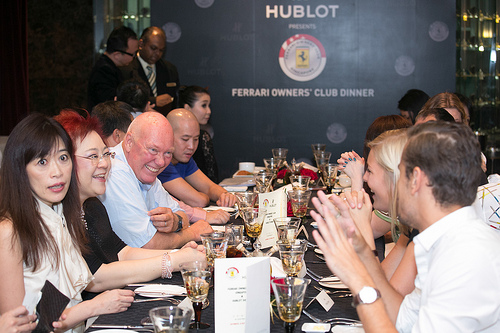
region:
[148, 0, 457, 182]
that's a sign on the wall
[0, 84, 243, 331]
there are five people sitting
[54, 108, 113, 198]
this lady has red hair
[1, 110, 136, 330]
this lady has long brown hair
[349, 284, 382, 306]
he has a watch on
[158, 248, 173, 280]
she has on some bracelets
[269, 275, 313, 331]
this is a wine glass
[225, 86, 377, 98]
this is the name of the club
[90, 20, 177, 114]
two men are talking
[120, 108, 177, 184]
this man has a bald head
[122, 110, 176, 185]
A bald man smiling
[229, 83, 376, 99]
'Ferrari Owners' Club Dinner' sign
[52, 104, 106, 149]
Red dyed color hair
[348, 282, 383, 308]
Round face wrist watch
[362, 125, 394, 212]
A blonde hair woman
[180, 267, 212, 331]
A clear glass of wine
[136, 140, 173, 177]
A man smiling face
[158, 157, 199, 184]
A navy blue short sleeves shirt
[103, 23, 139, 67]
Man wearing eye glasses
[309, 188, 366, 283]
Male hands in the air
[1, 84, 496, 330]
people sitting at a long table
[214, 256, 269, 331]
a white menu on a table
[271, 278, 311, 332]
a glass of white wine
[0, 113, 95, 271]
woman with long brown hair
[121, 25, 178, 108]
man wearing a suit and a tie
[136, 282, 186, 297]
a small white plate on a table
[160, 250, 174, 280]
woman wearing a bracelet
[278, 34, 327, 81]
a white and red logo on a blue wall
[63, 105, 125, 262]
woman with red hair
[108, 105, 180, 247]
man wearing light blue shirt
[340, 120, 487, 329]
man wearing a watch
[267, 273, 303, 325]
wine glass on table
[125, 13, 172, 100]
man wearing suit and tie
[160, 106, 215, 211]
man wearing dark blue shirt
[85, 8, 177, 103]
two men having a conversation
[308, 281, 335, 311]
name card on the table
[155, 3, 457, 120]
black sign with white letters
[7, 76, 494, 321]
a group of people at a table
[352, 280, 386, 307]
a watch on a man's wrist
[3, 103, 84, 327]
a lady with long dark hair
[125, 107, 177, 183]
a bald man's head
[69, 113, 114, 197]
the head of a lady wearing glasses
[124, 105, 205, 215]
2 bald men sitting together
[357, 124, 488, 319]
a man and woman enjoying themselves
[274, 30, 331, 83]
a Ferrari emblem on the wall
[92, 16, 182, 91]
2 men talking to each other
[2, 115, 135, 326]
a person is sitting down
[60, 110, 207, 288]
a person is sitting down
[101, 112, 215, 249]
a person is sitting down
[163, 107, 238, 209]
a person is sitting down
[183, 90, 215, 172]
a person is sitting down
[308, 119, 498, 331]
a person is sitting down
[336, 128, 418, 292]
a person is sitting down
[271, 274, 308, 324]
a vessel made for drinking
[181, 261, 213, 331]
a vessel made for drinking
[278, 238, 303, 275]
a vessel made for drinking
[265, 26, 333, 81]
logo on the wall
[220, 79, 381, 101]
white words on gray wall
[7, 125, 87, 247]
woman's long stringy black hair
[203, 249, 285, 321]
white menu on table top